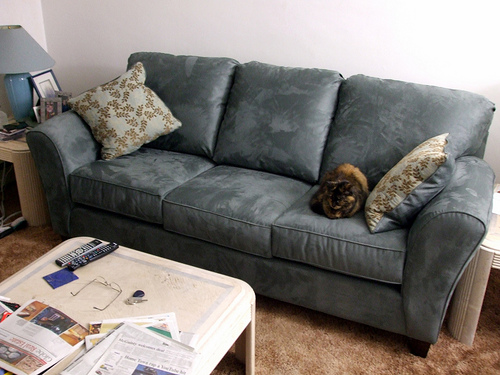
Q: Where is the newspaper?
A: On the table.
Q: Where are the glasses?
A: On the table.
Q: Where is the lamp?
A: On the table.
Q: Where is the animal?
A: On the couch.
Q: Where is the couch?
A: Near the wall.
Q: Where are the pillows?
A: On the couch.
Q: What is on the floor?
A: Carpet.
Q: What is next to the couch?
A: Tables.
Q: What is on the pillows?
A: Flowers.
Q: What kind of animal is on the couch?
A: A cat.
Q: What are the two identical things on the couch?
A: Pillows.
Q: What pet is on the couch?
A: A cat.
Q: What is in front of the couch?
A: A coffee table.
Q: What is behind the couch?
A: A wall.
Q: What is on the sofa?
A: A throw pillow.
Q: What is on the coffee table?
A: Papers.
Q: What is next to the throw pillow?
A: A cat.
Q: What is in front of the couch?
A: A small table.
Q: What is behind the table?
A: A small couch.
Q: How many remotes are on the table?
A: Two.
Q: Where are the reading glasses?
A: On the table.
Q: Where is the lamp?
A: Next to the sofa.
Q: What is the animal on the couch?
A: A cat.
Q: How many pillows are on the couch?
A: Two.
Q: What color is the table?
A: White.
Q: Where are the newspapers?
A: On the table.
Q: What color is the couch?
A: Blue.